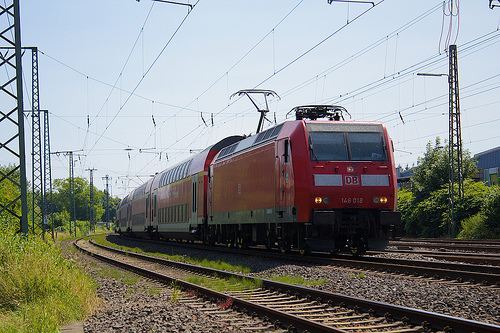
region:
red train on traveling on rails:
[91, 90, 411, 264]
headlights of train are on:
[305, 182, 395, 212]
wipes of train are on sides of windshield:
[291, 118, 392, 173]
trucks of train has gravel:
[188, 241, 498, 331]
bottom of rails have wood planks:
[67, 250, 334, 330]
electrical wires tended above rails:
[0, 0, 491, 111]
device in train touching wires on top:
[209, 67, 289, 130]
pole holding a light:
[407, 34, 477, 189]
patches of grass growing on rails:
[96, 242, 328, 332]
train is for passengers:
[96, 98, 407, 273]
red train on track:
[100, 124, 412, 255]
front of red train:
[278, 105, 402, 235]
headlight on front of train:
[310, 191, 335, 208]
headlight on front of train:
[372, 193, 394, 205]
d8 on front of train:
[344, 172, 360, 187]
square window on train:
[343, 125, 384, 160]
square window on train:
[301, 128, 353, 165]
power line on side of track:
[436, 29, 474, 233]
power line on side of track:
[40, 100, 63, 238]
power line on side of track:
[11, 33, 53, 244]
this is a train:
[100, 118, 401, 257]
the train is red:
[103, 107, 405, 251]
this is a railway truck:
[65, 233, 498, 331]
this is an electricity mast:
[446, 42, 478, 244]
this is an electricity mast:
[27, 41, 52, 241]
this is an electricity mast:
[44, 107, 61, 239]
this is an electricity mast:
[56, 144, 91, 246]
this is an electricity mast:
[87, 148, 104, 245]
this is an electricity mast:
[97, 165, 127, 241]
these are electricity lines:
[71, 77, 222, 147]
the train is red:
[62, 102, 293, 321]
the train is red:
[73, 36, 458, 313]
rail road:
[172, 265, 270, 322]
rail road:
[168, 257, 206, 282]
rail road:
[121, 208, 213, 318]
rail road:
[180, 255, 251, 300]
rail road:
[177, 271, 214, 305]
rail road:
[177, 215, 277, 322]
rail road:
[188, 237, 239, 318]